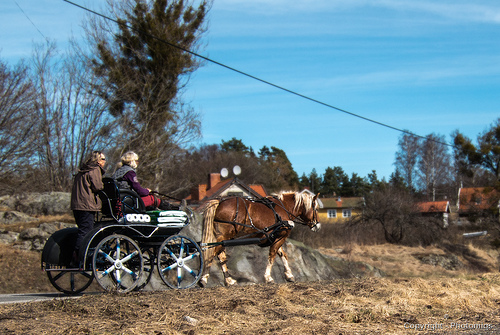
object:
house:
[314, 194, 367, 220]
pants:
[123, 195, 176, 215]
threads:
[213, 219, 268, 232]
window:
[328, 210, 338, 217]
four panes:
[328, 210, 335, 217]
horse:
[198, 186, 322, 286]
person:
[110, 150, 190, 212]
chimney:
[206, 171, 224, 190]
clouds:
[0, 0, 500, 180]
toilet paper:
[120, 214, 136, 224]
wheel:
[158, 234, 206, 291]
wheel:
[92, 235, 144, 296]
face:
[305, 191, 321, 231]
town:
[0, 0, 500, 334]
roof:
[459, 187, 500, 210]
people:
[73, 149, 108, 268]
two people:
[70, 150, 188, 269]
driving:
[113, 151, 166, 215]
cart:
[40, 176, 321, 294]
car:
[42, 176, 211, 295]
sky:
[0, 0, 500, 191]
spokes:
[121, 266, 142, 276]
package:
[117, 212, 151, 222]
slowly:
[42, 232, 294, 294]